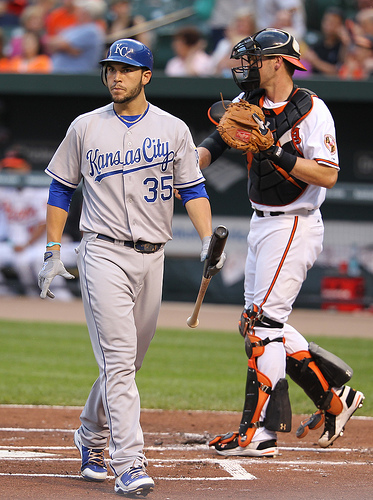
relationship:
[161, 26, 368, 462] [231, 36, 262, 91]
catcher wearing mask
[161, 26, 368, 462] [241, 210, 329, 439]
catcher wearing pants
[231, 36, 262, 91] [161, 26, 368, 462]
mask of catcher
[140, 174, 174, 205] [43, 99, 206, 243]
"35" across jersey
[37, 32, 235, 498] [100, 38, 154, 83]
batter wearing helmet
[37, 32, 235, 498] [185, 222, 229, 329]
batter holding bat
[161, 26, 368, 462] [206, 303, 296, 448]
catcher wearing guards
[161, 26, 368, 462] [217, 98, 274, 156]
catcher wearing mitt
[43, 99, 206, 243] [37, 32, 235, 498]
jersey across batter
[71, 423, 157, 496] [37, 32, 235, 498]
cleats of batter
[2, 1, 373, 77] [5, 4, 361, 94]
crowd in bleachers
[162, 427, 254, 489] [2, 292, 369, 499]
markings on baseball field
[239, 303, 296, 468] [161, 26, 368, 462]
guards of catcher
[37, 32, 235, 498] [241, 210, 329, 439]
batter wearing pants